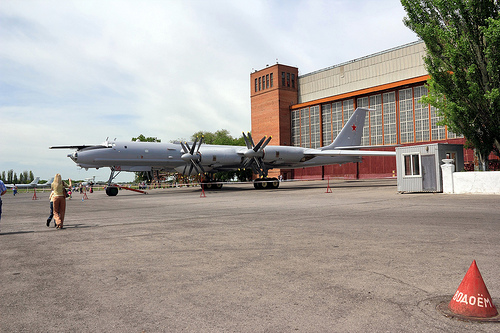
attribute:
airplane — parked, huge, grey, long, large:
[51, 104, 396, 189]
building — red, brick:
[251, 34, 499, 184]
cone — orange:
[450, 259, 500, 324]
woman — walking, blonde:
[48, 174, 68, 230]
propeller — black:
[239, 132, 273, 171]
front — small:
[69, 134, 162, 176]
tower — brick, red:
[250, 64, 300, 187]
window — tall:
[289, 109, 306, 152]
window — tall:
[382, 89, 398, 146]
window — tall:
[411, 85, 430, 142]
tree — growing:
[399, 2, 500, 173]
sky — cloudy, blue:
[3, 2, 440, 183]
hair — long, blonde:
[52, 177, 67, 196]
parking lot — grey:
[2, 186, 499, 330]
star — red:
[350, 123, 359, 135]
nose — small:
[69, 140, 153, 167]